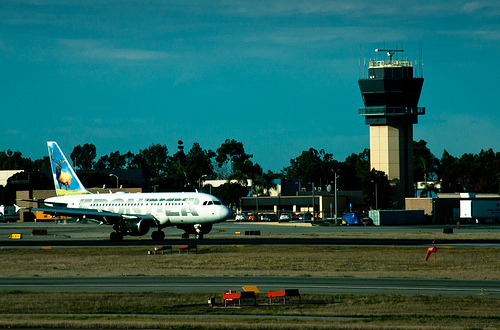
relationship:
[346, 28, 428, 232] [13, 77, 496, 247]
traffic tower at airport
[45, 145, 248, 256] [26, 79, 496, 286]
jetliner at airport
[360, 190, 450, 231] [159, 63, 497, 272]
storage building at airport